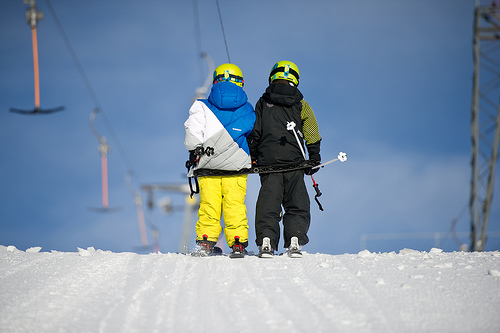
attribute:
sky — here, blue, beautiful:
[6, 1, 499, 244]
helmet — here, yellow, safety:
[210, 60, 245, 87]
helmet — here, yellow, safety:
[267, 62, 299, 84]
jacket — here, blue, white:
[187, 81, 258, 171]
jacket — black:
[250, 87, 323, 168]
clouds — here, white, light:
[315, 145, 497, 232]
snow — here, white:
[1, 235, 496, 330]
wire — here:
[31, 0, 230, 203]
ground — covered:
[4, 243, 497, 320]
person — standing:
[176, 58, 250, 257]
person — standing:
[242, 54, 330, 246]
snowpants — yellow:
[198, 174, 252, 240]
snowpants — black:
[255, 170, 314, 243]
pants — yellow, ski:
[193, 178, 249, 242]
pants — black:
[254, 171, 314, 240]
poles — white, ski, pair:
[285, 113, 352, 192]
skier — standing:
[183, 62, 263, 261]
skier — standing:
[244, 57, 327, 247]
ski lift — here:
[3, 3, 232, 249]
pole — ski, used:
[275, 152, 348, 178]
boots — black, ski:
[195, 237, 247, 253]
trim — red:
[202, 233, 243, 247]